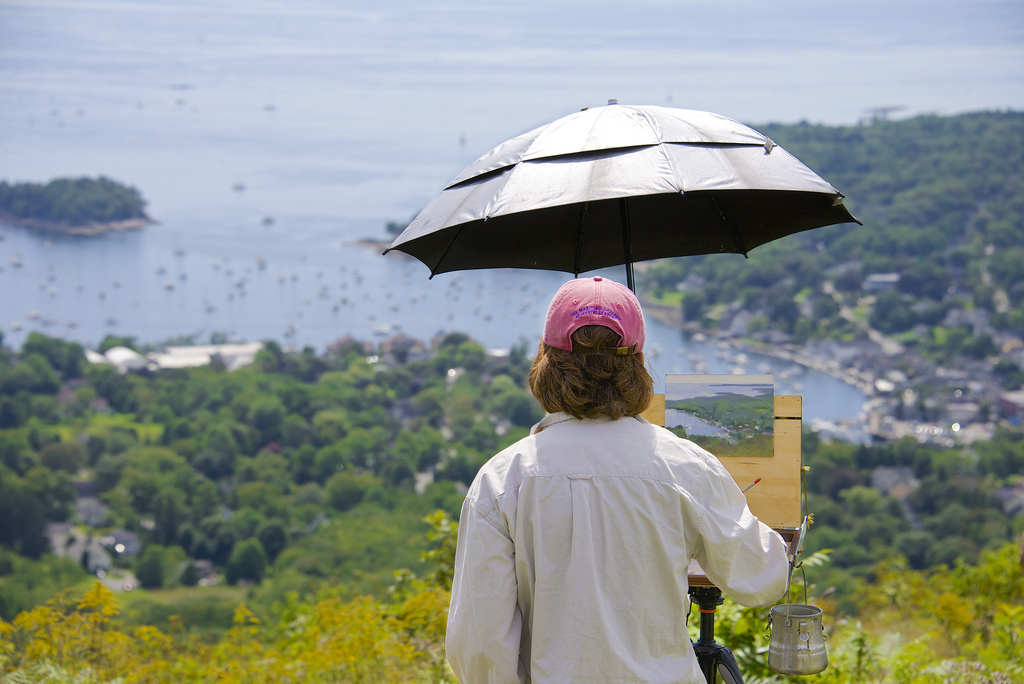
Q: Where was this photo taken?
A: Overlooking the ocean.